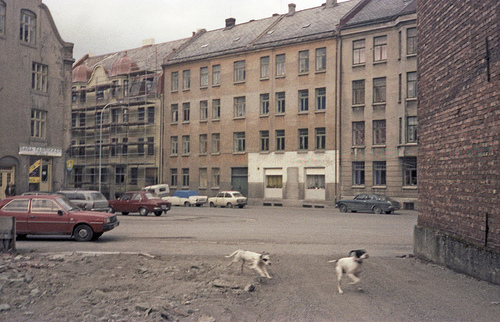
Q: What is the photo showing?
A: It is showing a street.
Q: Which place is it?
A: It is a street.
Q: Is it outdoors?
A: Yes, it is outdoors.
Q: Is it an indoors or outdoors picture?
A: It is outdoors.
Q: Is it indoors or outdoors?
A: It is outdoors.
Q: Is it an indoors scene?
A: No, it is outdoors.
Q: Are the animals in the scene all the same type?
A: Yes, all the animals are dogs.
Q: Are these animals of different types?
A: No, all the animals are dogs.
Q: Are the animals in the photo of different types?
A: No, all the animals are dogs.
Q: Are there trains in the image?
A: No, there are no trains.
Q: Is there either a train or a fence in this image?
A: No, there are no trains or fences.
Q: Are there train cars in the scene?
A: No, there are no train cars.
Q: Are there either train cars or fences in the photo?
A: No, there are no train cars or fences.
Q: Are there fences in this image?
A: No, there are no fences.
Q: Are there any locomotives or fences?
A: No, there are no fences or locomotives.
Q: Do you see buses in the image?
A: No, there are no buses.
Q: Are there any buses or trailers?
A: No, there are no buses or trailers.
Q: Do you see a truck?
A: No, there are no trucks.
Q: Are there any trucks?
A: No, there are no trucks.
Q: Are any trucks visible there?
A: No, there are no trucks.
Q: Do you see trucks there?
A: No, there are no trucks.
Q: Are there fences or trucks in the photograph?
A: No, there are no trucks or fences.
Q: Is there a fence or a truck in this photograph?
A: No, there are no trucks or fences.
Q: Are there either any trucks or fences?
A: No, there are no trucks or fences.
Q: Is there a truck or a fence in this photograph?
A: No, there are no trucks or fences.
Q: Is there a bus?
A: No, there are no buses.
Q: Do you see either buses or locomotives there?
A: No, there are no buses or locomotives.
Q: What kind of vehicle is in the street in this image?
A: The vehicle is a car.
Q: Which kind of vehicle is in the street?
A: The vehicle is a car.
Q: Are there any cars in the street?
A: Yes, there is a car in the street.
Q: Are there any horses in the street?
A: No, there is a car in the street.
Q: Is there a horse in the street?
A: No, there is a car in the street.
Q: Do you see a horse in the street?
A: No, there is a car in the street.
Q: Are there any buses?
A: No, there are no buses.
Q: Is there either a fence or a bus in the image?
A: No, there are no buses or fences.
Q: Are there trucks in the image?
A: No, there are no trucks.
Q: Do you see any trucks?
A: No, there are no trucks.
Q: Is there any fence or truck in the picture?
A: No, there are no trucks or fences.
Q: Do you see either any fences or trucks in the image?
A: No, there are no trucks or fences.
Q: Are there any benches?
A: No, there are no benches.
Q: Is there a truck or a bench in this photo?
A: No, there are no benches or trucks.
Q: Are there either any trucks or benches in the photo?
A: No, there are no benches or trucks.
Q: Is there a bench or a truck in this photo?
A: No, there are no benches or trucks.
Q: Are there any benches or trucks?
A: No, there are no benches or trucks.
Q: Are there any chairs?
A: No, there are no chairs.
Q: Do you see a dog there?
A: Yes, there are dogs.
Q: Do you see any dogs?
A: Yes, there are dogs.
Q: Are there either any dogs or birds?
A: Yes, there are dogs.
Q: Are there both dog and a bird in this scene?
A: No, there are dogs but no birds.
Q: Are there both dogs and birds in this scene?
A: No, there are dogs but no birds.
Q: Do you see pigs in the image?
A: No, there are no pigs.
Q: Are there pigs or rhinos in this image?
A: No, there are no pigs or rhinos.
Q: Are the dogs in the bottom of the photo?
A: Yes, the dogs are in the bottom of the image.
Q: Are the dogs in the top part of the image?
A: No, the dogs are in the bottom of the image.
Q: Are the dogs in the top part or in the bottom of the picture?
A: The dogs are in the bottom of the image.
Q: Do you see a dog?
A: Yes, there are dogs.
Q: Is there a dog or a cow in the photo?
A: Yes, there are dogs.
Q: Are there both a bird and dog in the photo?
A: No, there are dogs but no birds.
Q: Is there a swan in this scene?
A: No, there are no swans.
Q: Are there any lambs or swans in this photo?
A: No, there are no swans or lambs.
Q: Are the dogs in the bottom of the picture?
A: Yes, the dogs are in the bottom of the image.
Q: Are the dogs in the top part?
A: No, the dogs are in the bottom of the image.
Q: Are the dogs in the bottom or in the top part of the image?
A: The dogs are in the bottom of the image.